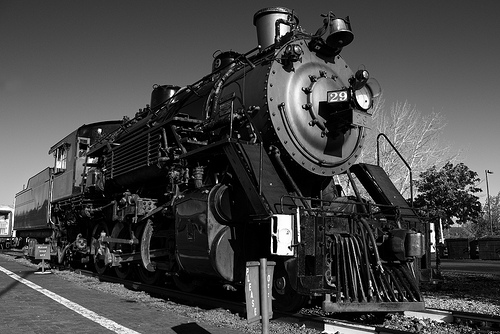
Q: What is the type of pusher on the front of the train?
A: Cow.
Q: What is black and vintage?
A: Train.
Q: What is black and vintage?
A: The train.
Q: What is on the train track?
A: A black vintage train.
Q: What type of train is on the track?
A: An old train.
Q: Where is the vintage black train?
A: On the tracks.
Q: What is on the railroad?
A: A locomotive.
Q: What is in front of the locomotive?
A: The number 29.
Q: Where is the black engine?
A: On the locomotive.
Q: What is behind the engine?
A: Cars.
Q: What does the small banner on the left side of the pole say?
A: Please.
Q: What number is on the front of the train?
A: 29.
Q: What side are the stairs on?
A: Right.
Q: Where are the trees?
A: Behind the train.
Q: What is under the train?
A: Train tracks.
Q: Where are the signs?
A: Beside the train.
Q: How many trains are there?
A: One.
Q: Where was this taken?
A: At a train station.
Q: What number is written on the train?
A: 29.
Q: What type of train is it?
A: A steam locomotive.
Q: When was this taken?
A: During the day.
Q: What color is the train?
A: Black.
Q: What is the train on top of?
A: Tracks.